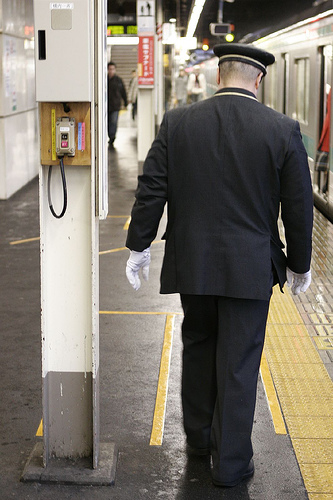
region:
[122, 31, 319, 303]
subway train conductor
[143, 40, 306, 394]
conductor of metro train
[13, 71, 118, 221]
conductor's telephone for metro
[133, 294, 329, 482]
yellow markings on subway platform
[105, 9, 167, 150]
stairs leading down to the subway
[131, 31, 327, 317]
train conductor in black suit and white gloves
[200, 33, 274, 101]
conductor's hat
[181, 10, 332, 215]
subway train arrived at platform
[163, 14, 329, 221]
subway train arrived at station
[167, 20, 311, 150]
conductor walking to train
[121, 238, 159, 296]
white glove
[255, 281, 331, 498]
yellow painted warning zone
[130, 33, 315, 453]
Railway employee in uniform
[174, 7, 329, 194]
silver subway train waiting at station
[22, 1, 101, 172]
electrical control box mounted on white post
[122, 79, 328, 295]
black jacket with gold trim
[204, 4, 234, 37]
security camera mounted in subway tunnel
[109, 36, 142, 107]
stairway to upper level of subway station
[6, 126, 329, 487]
grey subway platform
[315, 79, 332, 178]
passenger with red jacket and plaid skirt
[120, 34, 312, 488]
a person is walking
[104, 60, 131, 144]
a person is walking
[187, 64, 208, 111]
a person is walking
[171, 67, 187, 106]
a person is walking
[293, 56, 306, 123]
a window on a train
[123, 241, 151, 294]
a white glove on a hand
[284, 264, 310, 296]
a white glove on a hand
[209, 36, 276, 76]
a black hat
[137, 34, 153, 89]
a red sign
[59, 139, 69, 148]
a red button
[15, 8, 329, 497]
a subway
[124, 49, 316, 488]
a man in a black uniform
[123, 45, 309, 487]
the man in the black uniform has white gloves on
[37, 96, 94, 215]
a phone on the metal pole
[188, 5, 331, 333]
a train is at the platform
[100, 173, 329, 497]
yellow markings are on the floor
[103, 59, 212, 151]
people are on the subway platform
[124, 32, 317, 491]
the man works on the train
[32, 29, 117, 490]
a white and grey support post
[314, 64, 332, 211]
a person is entering or leaving the train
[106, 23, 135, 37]
a yellow sign above the door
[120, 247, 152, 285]
a white glove covering a hand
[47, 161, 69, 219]
a black cord on the telephone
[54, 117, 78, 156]
a black and red switch on the box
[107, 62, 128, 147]
a man wearing a black jacket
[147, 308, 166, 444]
yellow lines marking the platform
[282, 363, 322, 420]
a yellow slip resistant strip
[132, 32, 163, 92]
a red and white sign on a pole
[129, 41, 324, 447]
a man dressed in suit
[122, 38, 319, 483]
a man wearing a captain's hat